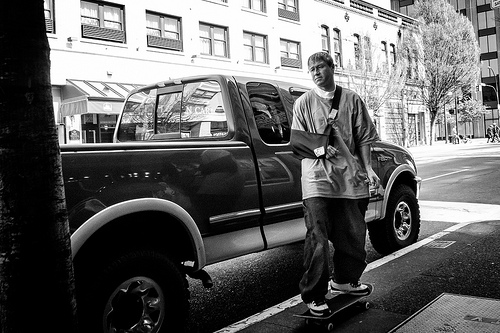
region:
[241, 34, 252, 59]
a window of a building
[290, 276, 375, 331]
a long black skateboard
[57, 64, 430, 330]
part of a large truck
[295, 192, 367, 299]
a boy's jean pants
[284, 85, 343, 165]
a black arm sling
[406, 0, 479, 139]
a large tree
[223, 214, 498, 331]
part of a sidewalk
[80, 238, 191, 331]
part of a large truck tire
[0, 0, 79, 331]
part of a tree trunk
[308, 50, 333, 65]
a man's short cut hair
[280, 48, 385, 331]
man on a skateboard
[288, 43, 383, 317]
man has his arm in a sling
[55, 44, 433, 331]
man on a skateboard in front of a truck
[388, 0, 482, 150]
tall tree next to a street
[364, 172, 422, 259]
front right wheel of a truck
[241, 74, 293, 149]
side window of a truck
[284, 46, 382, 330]
guy wears white sneakers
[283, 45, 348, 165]
right arm is in a sling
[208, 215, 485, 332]
straight line painted on a street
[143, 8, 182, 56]
window in a building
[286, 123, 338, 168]
he is wearing a sling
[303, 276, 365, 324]
he is riding the skateboard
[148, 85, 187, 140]
the window is closed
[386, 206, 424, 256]
the truck is parked by the curb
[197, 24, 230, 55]
the curtains are closed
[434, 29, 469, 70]
the tree has leaves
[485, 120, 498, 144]
they are walking together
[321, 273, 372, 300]
the shoes are white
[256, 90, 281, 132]
the window is tinted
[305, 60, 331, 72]
he is wearing glasses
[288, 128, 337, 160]
A sling being worn by a man on a skateboard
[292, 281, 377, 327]
A skateboard being ridden on a sidewalk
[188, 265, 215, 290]
An exhaust pipe on a truck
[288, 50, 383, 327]
A man riding a skateboard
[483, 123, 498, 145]
People walking across a street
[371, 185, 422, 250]
The front tire of a parked truck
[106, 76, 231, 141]
The rear windshield of a truck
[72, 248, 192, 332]
The rear tire of a parked truck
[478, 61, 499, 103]
Lights on top of a lamp post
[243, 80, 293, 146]
Rear window of a pick up truck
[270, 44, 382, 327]
Man riding on a skateboard.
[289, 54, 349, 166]
A man's right arm in a sling.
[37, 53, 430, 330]
A truck parked on the curb.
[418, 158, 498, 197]
A street with two lanes.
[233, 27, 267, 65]
A closed window.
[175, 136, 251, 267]
A man's reflection off the truck.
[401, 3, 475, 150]
A large tree near a building.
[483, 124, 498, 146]
People walking across the street.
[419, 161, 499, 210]
The pavement is flat.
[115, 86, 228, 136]
The truck's back window is closed.